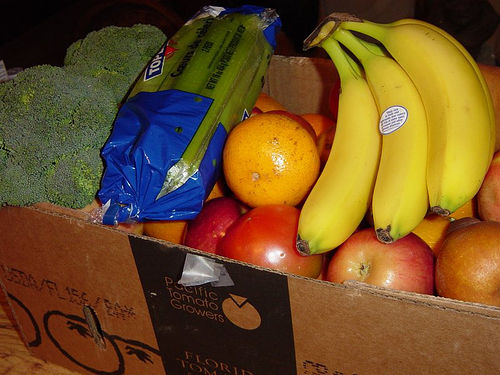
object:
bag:
[90, 0, 289, 224]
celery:
[93, 6, 282, 228]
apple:
[183, 197, 252, 253]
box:
[263, 55, 335, 117]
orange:
[223, 110, 326, 204]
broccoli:
[0, 20, 171, 209]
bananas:
[290, 11, 500, 258]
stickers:
[377, 104, 406, 136]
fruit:
[139, 12, 500, 310]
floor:
[0, 352, 51, 375]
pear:
[433, 221, 498, 305]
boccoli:
[0, 21, 175, 211]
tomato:
[220, 206, 318, 279]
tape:
[176, 253, 234, 288]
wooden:
[4, 325, 14, 372]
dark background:
[30, 10, 76, 31]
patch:
[130, 264, 191, 351]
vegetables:
[0, 5, 283, 212]